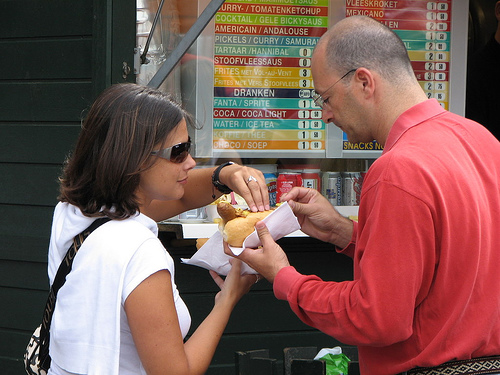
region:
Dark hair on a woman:
[21, 82, 219, 257]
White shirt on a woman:
[25, 192, 263, 372]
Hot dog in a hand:
[203, 172, 340, 278]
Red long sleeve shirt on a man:
[291, 99, 496, 372]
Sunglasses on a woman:
[80, 105, 225, 174]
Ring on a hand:
[216, 160, 294, 235]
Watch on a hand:
[203, 151, 250, 198]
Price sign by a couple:
[198, 14, 435, 192]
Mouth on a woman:
[168, 173, 210, 199]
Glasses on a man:
[301, 55, 379, 126]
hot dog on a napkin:
[213, 199, 300, 246]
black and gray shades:
[155, 136, 195, 160]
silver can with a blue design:
[323, 169, 342, 204]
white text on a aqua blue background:
[213, 98, 300, 108]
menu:
[213, 52, 458, 149]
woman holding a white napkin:
[23, 80, 259, 373]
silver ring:
[246, 174, 258, 186]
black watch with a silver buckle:
[211, 160, 238, 192]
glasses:
[308, 66, 378, 104]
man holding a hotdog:
[216, 11, 498, 373]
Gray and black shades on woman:
[155, 142, 197, 161]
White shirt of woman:
[81, 269, 115, 340]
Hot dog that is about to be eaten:
[218, 199, 249, 238]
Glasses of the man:
[311, 83, 328, 108]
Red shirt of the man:
[408, 180, 469, 261]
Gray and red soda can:
[343, 168, 364, 207]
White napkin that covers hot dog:
[275, 213, 292, 234]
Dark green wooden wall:
[16, 27, 76, 96]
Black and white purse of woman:
[23, 337, 50, 374]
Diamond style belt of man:
[447, 357, 499, 372]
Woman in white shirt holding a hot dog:
[30, 76, 297, 371]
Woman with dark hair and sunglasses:
[20, 70, 205, 221]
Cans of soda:
[320, 170, 362, 202]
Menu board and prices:
[210, 11, 310, 147]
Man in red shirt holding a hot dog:
[211, 10, 496, 370]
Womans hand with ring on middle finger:
[230, 165, 271, 210]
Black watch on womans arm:
[201, 150, 237, 190]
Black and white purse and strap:
[12, 207, 117, 369]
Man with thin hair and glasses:
[300, 12, 454, 151]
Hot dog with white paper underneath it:
[212, 203, 308, 256]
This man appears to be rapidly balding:
[338, 28, 373, 60]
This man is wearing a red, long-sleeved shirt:
[428, 160, 458, 217]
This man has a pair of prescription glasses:
[308, 74, 346, 119]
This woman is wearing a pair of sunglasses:
[156, 140, 191, 162]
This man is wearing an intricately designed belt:
[471, 355, 491, 373]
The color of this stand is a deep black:
[22, 62, 39, 134]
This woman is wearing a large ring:
[246, 176, 265, 190]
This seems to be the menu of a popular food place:
[233, 12, 288, 132]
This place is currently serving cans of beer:
[306, 175, 333, 202]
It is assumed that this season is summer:
[116, 44, 413, 347]